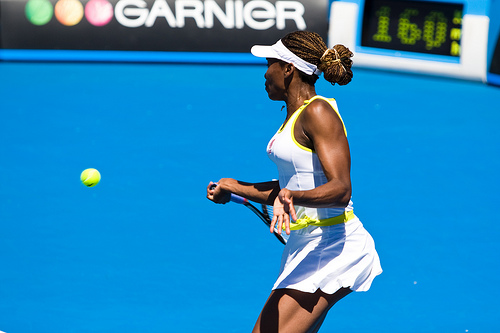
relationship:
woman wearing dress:
[210, 31, 382, 332] [261, 96, 385, 297]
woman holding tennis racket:
[210, 31, 382, 332] [224, 184, 285, 249]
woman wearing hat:
[210, 31, 382, 332] [248, 43, 319, 79]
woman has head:
[210, 31, 382, 332] [263, 29, 324, 102]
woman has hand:
[210, 31, 382, 332] [269, 186, 300, 234]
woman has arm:
[210, 31, 382, 332] [295, 102, 354, 207]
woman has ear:
[210, 31, 382, 332] [282, 62, 295, 79]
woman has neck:
[210, 31, 382, 332] [283, 76, 318, 114]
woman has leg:
[210, 31, 382, 332] [255, 238, 356, 331]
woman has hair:
[210, 31, 382, 332] [281, 28, 354, 87]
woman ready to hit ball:
[210, 31, 382, 332] [80, 168, 100, 188]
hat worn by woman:
[248, 43, 319, 79] [210, 31, 382, 332]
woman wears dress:
[210, 31, 382, 332] [261, 96, 385, 297]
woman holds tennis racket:
[210, 31, 382, 332] [224, 184, 285, 249]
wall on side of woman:
[1, 49, 498, 327] [210, 31, 382, 332]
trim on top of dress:
[281, 96, 347, 154] [261, 96, 385, 297]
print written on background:
[112, 0, 308, 29] [1, 3, 330, 53]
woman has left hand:
[210, 31, 382, 332] [269, 186, 300, 234]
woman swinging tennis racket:
[210, 31, 382, 332] [224, 184, 285, 249]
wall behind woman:
[1, 49, 498, 327] [210, 31, 382, 332]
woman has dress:
[210, 31, 382, 332] [261, 96, 385, 297]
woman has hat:
[210, 31, 382, 332] [248, 43, 319, 79]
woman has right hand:
[210, 31, 382, 332] [209, 177, 233, 204]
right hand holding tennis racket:
[209, 177, 233, 204] [224, 184, 285, 249]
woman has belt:
[210, 31, 382, 332] [286, 210, 357, 232]